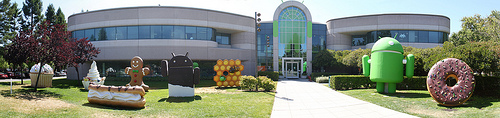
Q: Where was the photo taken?
A: It was taken at the field.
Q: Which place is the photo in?
A: It is at the field.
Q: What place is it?
A: It is a field.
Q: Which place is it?
A: It is a field.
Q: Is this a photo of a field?
A: Yes, it is showing a field.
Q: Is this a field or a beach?
A: It is a field.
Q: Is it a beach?
A: No, it is a field.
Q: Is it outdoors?
A: Yes, it is outdoors.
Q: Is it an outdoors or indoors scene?
A: It is outdoors.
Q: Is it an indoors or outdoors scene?
A: It is outdoors.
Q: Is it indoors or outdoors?
A: It is outdoors.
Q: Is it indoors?
A: No, it is outdoors.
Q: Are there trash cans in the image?
A: No, there are no trash cans.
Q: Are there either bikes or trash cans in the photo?
A: No, there are no trash cans or bikes.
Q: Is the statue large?
A: Yes, the statue is large.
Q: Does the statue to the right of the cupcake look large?
A: Yes, the statue is large.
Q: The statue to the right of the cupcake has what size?
A: The statue is large.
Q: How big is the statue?
A: The statue is large.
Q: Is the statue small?
A: No, the statue is large.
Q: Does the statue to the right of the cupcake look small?
A: No, the statue is large.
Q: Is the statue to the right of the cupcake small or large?
A: The statue is large.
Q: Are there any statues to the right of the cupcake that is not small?
A: Yes, there is a statue to the right of the cupcake.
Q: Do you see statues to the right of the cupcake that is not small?
A: Yes, there is a statue to the right of the cupcake.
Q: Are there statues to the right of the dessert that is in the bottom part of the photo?
A: Yes, there is a statue to the right of the cupcake.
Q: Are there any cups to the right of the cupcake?
A: No, there is a statue to the right of the cupcake.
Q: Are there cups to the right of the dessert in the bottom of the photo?
A: No, there is a statue to the right of the cupcake.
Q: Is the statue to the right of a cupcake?
A: Yes, the statue is to the right of a cupcake.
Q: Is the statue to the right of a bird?
A: No, the statue is to the right of a cupcake.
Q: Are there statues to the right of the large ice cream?
A: Yes, there is a statue to the right of the ice cream.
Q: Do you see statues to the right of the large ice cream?
A: Yes, there is a statue to the right of the ice cream.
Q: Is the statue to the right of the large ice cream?
A: Yes, the statue is to the right of the ice cream.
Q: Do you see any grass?
A: Yes, there is grass.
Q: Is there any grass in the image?
A: Yes, there is grass.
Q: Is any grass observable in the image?
A: Yes, there is grass.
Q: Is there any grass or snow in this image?
A: Yes, there is grass.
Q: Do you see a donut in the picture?
A: Yes, there is a donut.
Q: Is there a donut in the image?
A: Yes, there is a donut.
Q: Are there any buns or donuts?
A: Yes, there is a donut.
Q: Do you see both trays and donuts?
A: No, there is a donut but no trays.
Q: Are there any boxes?
A: No, there are no boxes.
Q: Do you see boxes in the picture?
A: No, there are no boxes.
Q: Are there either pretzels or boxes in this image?
A: No, there are no boxes or pretzels.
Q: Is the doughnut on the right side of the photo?
A: Yes, the doughnut is on the right of the image.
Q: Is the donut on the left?
A: No, the donut is on the right of the image.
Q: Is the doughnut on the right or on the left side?
A: The doughnut is on the right of the image.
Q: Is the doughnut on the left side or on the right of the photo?
A: The doughnut is on the right of the image.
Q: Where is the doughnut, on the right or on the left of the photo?
A: The doughnut is on the right of the image.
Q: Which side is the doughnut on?
A: The doughnut is on the right of the image.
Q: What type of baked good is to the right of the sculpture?
A: The food is a donut.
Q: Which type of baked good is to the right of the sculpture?
A: The food is a donut.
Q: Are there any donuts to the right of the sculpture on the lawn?
A: Yes, there is a donut to the right of the sculpture.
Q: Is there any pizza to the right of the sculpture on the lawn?
A: No, there is a donut to the right of the sculpture.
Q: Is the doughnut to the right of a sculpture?
A: Yes, the doughnut is to the right of a sculpture.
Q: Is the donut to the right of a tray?
A: No, the donut is to the right of a sculpture.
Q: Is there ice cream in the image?
A: Yes, there is ice cream.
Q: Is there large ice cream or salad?
A: Yes, there is large ice cream.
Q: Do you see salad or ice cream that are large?
A: Yes, the ice cream is large.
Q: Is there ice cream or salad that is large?
A: Yes, the ice cream is large.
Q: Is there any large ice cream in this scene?
A: Yes, there is large ice cream.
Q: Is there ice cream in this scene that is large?
A: Yes, there is ice cream that is large.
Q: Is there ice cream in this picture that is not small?
A: Yes, there is large ice cream.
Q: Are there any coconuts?
A: No, there are no coconuts.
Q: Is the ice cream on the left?
A: Yes, the ice cream is on the left of the image.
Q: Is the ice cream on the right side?
A: No, the ice cream is on the left of the image.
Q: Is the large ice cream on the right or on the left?
A: The ice cream is on the left of the image.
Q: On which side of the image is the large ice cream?
A: The ice cream is on the left of the image.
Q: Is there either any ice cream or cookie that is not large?
A: No, there is ice cream but it is large.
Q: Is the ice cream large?
A: Yes, the ice cream is large.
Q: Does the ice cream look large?
A: Yes, the ice cream is large.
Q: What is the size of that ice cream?
A: The ice cream is large.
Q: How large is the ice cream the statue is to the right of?
A: The ice cream is large.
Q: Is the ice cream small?
A: No, the ice cream is large.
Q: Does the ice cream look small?
A: No, the ice cream is large.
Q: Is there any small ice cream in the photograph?
A: No, there is ice cream but it is large.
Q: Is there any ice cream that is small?
A: No, there is ice cream but it is large.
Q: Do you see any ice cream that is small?
A: No, there is ice cream but it is large.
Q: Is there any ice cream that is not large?
A: No, there is ice cream but it is large.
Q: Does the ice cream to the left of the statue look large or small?
A: The ice cream is large.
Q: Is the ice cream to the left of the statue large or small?
A: The ice cream is large.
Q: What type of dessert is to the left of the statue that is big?
A: The dessert is ice cream.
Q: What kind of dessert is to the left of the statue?
A: The dessert is ice cream.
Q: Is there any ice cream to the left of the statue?
A: Yes, there is ice cream to the left of the statue.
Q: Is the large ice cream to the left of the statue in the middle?
A: Yes, the ice cream is to the left of the statue.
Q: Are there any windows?
A: Yes, there is a window.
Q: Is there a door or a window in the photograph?
A: Yes, there is a window.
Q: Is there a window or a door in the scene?
A: Yes, there is a window.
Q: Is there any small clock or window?
A: Yes, there is a small window.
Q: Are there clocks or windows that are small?
A: Yes, the window is small.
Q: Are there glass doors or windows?
A: Yes, there is a glass window.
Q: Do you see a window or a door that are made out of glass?
A: Yes, the window is made of glass.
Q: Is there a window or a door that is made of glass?
A: Yes, the window is made of glass.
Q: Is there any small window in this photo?
A: Yes, there is a small window.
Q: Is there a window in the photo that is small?
A: Yes, there is a window that is small.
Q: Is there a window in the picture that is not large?
A: Yes, there is a small window.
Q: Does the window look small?
A: Yes, the window is small.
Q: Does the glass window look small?
A: Yes, the window is small.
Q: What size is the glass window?
A: The window is small.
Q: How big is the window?
A: The window is small.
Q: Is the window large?
A: No, the window is small.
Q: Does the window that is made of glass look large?
A: No, the window is small.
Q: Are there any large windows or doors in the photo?
A: No, there is a window but it is small.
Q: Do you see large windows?
A: No, there is a window but it is small.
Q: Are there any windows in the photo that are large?
A: No, there is a window but it is small.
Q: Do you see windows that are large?
A: No, there is a window but it is small.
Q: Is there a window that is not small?
A: No, there is a window but it is small.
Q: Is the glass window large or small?
A: The window is small.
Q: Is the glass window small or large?
A: The window is small.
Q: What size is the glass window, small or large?
A: The window is small.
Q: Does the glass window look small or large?
A: The window is small.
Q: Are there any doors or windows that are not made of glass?
A: No, there is a window but it is made of glass.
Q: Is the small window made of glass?
A: Yes, the window is made of glass.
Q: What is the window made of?
A: The window is made of glass.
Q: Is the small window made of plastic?
A: No, the window is made of glass.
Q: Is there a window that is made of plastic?
A: No, there is a window but it is made of glass.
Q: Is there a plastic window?
A: No, there is a window but it is made of glass.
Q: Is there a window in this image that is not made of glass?
A: No, there is a window but it is made of glass.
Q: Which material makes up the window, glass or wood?
A: The window is made of glass.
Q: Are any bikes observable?
A: No, there are no bikes.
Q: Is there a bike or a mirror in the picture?
A: No, there are no bikes or mirrors.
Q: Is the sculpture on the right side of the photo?
A: Yes, the sculpture is on the right of the image.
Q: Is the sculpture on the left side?
A: No, the sculpture is on the right of the image.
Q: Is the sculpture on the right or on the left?
A: The sculpture is on the right of the image.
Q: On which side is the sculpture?
A: The sculpture is on the right of the image.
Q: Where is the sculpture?
A: The sculpture is on the lawn.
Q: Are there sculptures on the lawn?
A: Yes, there is a sculpture on the lawn.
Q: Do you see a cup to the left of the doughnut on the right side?
A: No, there is a sculpture to the left of the doughnut.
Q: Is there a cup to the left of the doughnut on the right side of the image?
A: No, there is a sculpture to the left of the doughnut.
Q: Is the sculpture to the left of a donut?
A: Yes, the sculpture is to the left of a donut.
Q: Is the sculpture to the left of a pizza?
A: No, the sculpture is to the left of a donut.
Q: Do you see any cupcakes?
A: Yes, there is a cupcake.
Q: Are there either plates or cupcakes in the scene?
A: Yes, there is a cupcake.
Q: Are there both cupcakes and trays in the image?
A: No, there is a cupcake but no trays.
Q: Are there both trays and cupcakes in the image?
A: No, there is a cupcake but no trays.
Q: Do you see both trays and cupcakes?
A: No, there is a cupcake but no trays.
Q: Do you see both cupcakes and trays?
A: No, there is a cupcake but no trays.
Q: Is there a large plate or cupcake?
A: Yes, there is a large cupcake.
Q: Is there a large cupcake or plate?
A: Yes, there is a large cupcake.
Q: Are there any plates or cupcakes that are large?
A: Yes, the cupcake is large.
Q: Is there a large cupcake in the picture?
A: Yes, there is a large cupcake.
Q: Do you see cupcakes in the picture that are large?
A: Yes, there is a cupcake that is large.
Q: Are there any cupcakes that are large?
A: Yes, there is a cupcake that is large.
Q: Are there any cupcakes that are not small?
A: Yes, there is a large cupcake.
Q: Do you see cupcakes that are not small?
A: Yes, there is a large cupcake.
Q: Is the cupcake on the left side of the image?
A: Yes, the cupcake is on the left of the image.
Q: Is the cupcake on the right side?
A: No, the cupcake is on the left of the image.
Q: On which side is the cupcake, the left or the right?
A: The cupcake is on the left of the image.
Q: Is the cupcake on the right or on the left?
A: The cupcake is on the left of the image.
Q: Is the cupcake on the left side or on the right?
A: The cupcake is on the left of the image.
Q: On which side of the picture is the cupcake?
A: The cupcake is on the left of the image.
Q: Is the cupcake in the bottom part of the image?
A: Yes, the cupcake is in the bottom of the image.